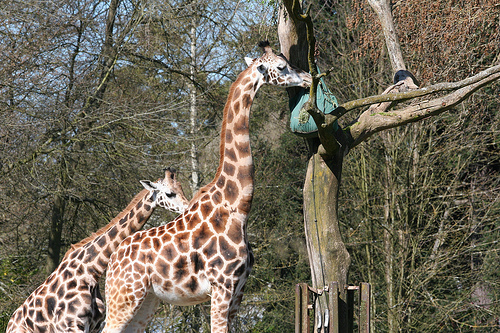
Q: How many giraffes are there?
A: Two.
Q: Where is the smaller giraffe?
A: To the left.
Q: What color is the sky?
A: Blue.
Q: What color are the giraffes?
A: Brown and white.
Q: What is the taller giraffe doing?
A: Eating something in the tree.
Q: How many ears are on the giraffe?
A: Two.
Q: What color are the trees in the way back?
A: Green.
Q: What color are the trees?
A: Brown and green.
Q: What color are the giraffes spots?
A: Brown.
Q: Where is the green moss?
A: On the tree.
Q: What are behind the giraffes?
A: Bare tall trees.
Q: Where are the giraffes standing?
A: On the ground.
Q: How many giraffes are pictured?
A: Two.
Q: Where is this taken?
A: At a zoo.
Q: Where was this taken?
A: Zoo.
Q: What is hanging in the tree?
A: Giraffe food.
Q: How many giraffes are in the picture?
A: Two.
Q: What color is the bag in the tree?
A: Green.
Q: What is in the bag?
A: Food.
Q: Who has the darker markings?
A: The giraffe on the left.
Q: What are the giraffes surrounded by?
A: Trees.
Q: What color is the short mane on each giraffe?
A: Orange.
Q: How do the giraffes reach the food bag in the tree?
A: The giraffes have long necks.